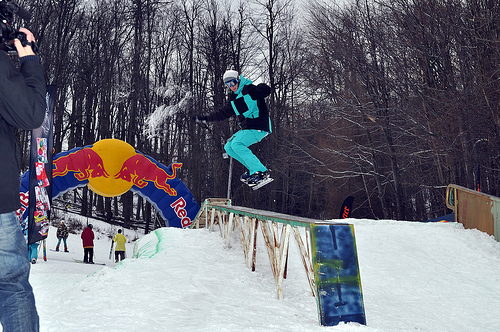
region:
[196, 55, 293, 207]
This is a person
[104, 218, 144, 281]
This is a person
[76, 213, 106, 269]
This is a person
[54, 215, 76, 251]
This is a person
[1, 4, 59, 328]
This is a person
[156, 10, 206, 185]
These are many trees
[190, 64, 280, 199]
The person is in the air.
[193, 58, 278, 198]
The person is on a snowboard.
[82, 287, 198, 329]
The snow is white in color.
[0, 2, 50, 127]
The man is holding a video camera.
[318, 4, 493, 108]
The trees in the background are bare.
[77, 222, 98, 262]
The person is wearing a red coat.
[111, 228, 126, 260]
The person is wearing a yellow coat.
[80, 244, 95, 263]
The person is wearing black pants.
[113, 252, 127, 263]
The person is wearing black pants.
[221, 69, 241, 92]
The person is wearing ski goggles.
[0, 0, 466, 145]
light in daytime sky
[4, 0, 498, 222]
trees with no leaves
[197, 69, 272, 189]
snowboarder jumping in the air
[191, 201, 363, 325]
long platform in snow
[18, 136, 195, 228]
balloon banner with logo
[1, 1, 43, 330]
person with camera in hand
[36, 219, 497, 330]
white snow on ground surface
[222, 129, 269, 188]
bent knees of snowboarder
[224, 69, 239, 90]
hat and goggles on head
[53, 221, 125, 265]
people standing on snow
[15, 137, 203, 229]
Red Bull promotional balloon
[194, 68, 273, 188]
person using a snowboard jumping in the air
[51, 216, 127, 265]
small group of people on skis and snowboards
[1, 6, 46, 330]
man wearing jeans holding a camera filming a snowboarder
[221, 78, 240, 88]
ski glasses being worn by a person riding a snow boarder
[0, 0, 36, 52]
video camera being held by a man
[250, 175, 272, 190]
snowboard attached to a person wearing a light blue ski suit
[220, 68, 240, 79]
white snow cap worn by a snow boarder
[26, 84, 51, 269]
large black cloth banner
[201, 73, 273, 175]
ski suit worn by a snowboarder colored pale teal and black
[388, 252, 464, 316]
the snow is white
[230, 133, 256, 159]
light green pants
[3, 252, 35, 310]
blue jeans pants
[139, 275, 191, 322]
white snow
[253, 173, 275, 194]
a snowboard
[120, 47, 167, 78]
tree branches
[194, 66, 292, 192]
a snow boarder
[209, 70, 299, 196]
the snow boarder in the air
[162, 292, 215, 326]
the snow on the ground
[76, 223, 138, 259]
people skiing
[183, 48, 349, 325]
Skateboarder jumping over barrier.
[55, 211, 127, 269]
People standing in snow.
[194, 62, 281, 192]
Man wearing white hat.